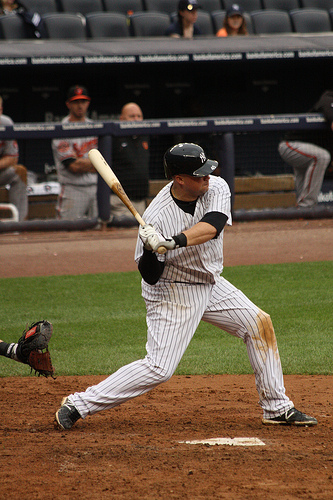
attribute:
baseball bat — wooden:
[89, 149, 167, 255]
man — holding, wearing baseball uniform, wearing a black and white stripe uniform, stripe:
[55, 138, 317, 426]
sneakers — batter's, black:
[51, 394, 320, 433]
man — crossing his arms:
[51, 83, 100, 223]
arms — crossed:
[54, 139, 97, 174]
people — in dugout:
[35, 58, 157, 214]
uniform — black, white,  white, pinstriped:
[66, 173, 295, 420]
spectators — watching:
[169, 0, 247, 36]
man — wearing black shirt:
[110, 93, 170, 233]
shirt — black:
[109, 128, 152, 204]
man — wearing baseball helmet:
[146, 151, 279, 323]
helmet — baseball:
[183, 144, 225, 178]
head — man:
[164, 137, 222, 196]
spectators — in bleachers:
[166, 0, 253, 43]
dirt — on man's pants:
[247, 303, 293, 358]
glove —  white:
[148, 231, 175, 252]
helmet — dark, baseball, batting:
[162, 142, 218, 179]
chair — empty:
[43, 12, 85, 37]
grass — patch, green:
[258, 258, 327, 309]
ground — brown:
[251, 218, 316, 289]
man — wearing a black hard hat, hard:
[66, 122, 299, 374]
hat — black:
[155, 124, 233, 179]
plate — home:
[168, 396, 278, 485]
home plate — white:
[184, 425, 263, 451]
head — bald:
[120, 102, 143, 120]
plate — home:
[179, 428, 270, 462]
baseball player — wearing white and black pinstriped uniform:
[55, 122, 314, 448]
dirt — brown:
[90, 446, 208, 483]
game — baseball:
[2, 15, 331, 493]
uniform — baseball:
[127, 181, 280, 415]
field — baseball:
[21, 236, 129, 314]